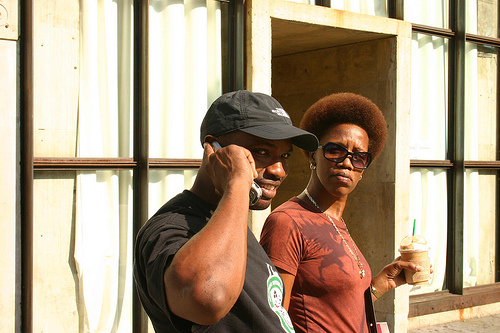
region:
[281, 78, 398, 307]
This is a person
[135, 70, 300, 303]
This is a person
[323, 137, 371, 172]
sunglasses on woman's face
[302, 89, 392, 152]
afro on woman's head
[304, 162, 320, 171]
earring on right ear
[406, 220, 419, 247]
green straw in drink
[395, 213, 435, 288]
brown beverage in hand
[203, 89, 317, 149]
hat on man's head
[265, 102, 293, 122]
white logo on hat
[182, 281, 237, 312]
the man's right elbow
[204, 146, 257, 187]
the man's right hand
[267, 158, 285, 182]
nose on the man's face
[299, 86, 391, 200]
head of a person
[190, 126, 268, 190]
hand of a person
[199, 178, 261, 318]
arm of a person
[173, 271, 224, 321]
elbow of a person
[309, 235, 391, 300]
breast of a person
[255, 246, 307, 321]
arm of a person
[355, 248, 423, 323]
arm of a person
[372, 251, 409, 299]
wrist of a person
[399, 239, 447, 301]
hand of a person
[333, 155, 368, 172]
nose of a person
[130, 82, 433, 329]
Man and woman looking in the same direction.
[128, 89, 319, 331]
Man wearing a black baseball cap.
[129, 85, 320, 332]
Man wearing a black shirt.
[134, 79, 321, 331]
Man using cellphone in his right hand.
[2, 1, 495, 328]
Sun shining brightly on a sunny day.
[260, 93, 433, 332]
Adult woman wearing sunglasses.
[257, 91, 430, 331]
Woman wearing gold hoop earrings.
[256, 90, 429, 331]
Woman wearing silver necklace.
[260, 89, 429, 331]
Woman holding coffee drink in her left hand.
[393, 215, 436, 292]
Green straw inside the coffee drink.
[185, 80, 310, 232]
a man with phone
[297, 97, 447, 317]
woman holding a cup